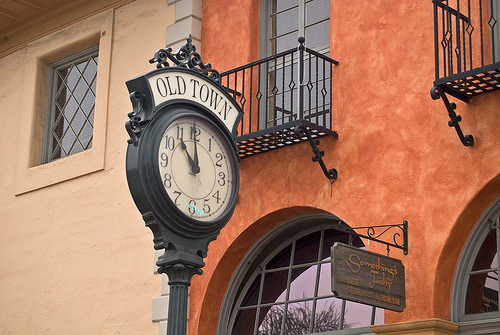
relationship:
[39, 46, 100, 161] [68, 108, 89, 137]
window has pane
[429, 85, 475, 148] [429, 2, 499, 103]
bracket supports balcony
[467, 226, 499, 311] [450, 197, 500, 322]
window has frame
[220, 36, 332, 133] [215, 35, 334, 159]
fence on balcony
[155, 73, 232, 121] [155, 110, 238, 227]
writing above clock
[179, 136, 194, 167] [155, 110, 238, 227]
hand on clock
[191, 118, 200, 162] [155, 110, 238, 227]
hand on clock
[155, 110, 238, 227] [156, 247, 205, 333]
clock on pole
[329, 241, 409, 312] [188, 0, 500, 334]
sign hanging from building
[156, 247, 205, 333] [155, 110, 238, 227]
pole supporting clock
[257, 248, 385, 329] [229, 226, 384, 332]
reflection in window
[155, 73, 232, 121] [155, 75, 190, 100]
writing has word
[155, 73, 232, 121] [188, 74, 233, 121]
writing has word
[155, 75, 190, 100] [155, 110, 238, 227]
word over clock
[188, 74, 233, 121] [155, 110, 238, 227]
word over clock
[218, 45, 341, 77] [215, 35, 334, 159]
railing on balcony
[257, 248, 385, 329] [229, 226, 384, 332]
reflection on window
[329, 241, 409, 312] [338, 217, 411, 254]
sign hanging from brace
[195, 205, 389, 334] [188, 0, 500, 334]
arch in wall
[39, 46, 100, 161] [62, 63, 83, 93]
window has pane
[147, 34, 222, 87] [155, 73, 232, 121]
decoration above writing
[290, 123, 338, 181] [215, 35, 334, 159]
brace under balcony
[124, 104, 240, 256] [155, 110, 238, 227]
frame around clock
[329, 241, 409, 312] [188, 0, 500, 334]
sign attached to wall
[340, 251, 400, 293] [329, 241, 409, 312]
name on sign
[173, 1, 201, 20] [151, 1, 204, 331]
brick in row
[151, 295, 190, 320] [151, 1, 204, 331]
brick in row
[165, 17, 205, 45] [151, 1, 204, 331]
brick in row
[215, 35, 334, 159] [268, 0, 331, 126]
balcony beneath window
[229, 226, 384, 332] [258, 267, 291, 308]
window has pane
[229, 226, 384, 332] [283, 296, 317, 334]
window has pane